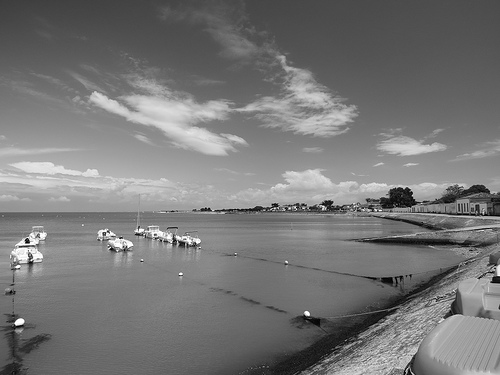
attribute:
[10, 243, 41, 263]
speed boat — white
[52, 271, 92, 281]
spot — dark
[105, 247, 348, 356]
seas — calm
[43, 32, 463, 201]
sky — clear 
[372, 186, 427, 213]
tree — big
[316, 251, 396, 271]
spot — dark 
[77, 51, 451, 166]
clouds — white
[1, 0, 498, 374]
scene — black, white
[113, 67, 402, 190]
cloud formation — heavy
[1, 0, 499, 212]
clouds — white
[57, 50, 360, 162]
cloud formation — high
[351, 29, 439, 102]
sky — dark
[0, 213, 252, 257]
water — ocean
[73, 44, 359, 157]
clouds — white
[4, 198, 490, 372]
water — transparent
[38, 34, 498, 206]
weather — nice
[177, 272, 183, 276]
buoey — small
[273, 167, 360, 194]
clouds — white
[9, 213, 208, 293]
boats — white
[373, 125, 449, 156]
cloud — white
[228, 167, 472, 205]
cloud — white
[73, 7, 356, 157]
cloud — white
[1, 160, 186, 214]
cloud — white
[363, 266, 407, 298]
spot — dark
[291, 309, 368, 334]
spot — dark 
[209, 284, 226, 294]
spot — dark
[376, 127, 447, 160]
cloud — white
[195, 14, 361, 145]
cloud — white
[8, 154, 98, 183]
cloud — white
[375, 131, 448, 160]
cloud — white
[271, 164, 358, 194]
cloud — white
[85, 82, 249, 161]
cloud — white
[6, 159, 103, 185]
cloud — white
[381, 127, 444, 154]
cloud — white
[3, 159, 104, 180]
cloud — white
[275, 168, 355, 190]
cloud — white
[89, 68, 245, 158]
cloud — white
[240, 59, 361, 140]
cloud — white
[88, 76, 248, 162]
cloud — white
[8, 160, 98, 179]
cloud — white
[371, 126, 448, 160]
cloud — white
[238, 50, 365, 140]
cloud — white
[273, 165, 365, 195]
cloud — white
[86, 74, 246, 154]
cloud — white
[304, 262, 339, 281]
spot — dark 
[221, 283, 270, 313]
spot — dark 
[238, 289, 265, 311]
spot — dark